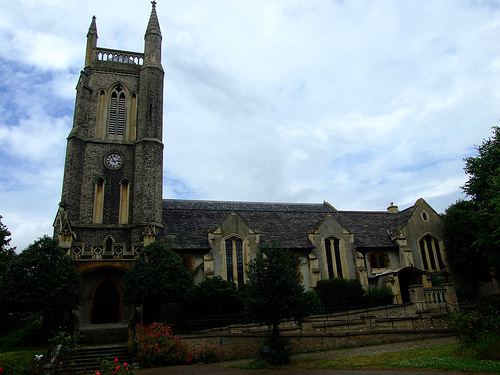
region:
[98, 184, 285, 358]
A building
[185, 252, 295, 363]
A building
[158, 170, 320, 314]
A building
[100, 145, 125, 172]
a white clock on building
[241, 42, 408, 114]
white clouds in the sky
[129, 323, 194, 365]
pink flowers near stairs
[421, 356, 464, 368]
green grass on the ground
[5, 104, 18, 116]
blue sky between clouds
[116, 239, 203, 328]
a triangular shaped tree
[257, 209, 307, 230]
a dark grey roof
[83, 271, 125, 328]
an arched doorway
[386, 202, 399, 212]
a chimney on building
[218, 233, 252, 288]
a window on a building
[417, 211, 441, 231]
the window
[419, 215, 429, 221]
the window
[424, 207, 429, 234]
the window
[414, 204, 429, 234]
the window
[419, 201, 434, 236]
the window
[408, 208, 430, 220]
the window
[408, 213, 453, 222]
the window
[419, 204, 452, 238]
the window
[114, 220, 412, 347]
A building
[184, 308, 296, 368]
A building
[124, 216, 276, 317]
A building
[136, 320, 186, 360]
Red flowers.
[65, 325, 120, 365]
Stairs to the church.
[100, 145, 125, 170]
The tower has a clock on it.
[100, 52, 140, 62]
The tower has a small dome.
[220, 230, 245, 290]
The window is narrow.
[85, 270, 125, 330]
A dark main entrance.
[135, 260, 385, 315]
Trees along the wall.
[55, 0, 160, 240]
The tower is made of stone.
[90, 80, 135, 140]
Very old wooden window.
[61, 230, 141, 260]
Artistically designed wall.